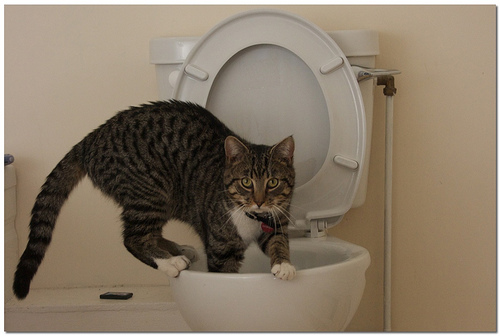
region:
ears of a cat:
[219, 133, 299, 162]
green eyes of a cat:
[232, 175, 282, 192]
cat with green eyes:
[72, 90, 317, 290]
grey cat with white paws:
[3, 96, 309, 312]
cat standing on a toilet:
[17, 95, 307, 303]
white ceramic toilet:
[146, 11, 382, 328]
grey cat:
[0, 87, 306, 333]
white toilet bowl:
[153, 237, 385, 334]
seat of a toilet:
[175, 10, 369, 240]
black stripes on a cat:
[86, 110, 226, 215]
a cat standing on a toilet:
[6, 10, 381, 308]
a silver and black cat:
[10, 95, 305, 305]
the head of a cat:
[219, 132, 299, 215]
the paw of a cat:
[266, 257, 302, 287]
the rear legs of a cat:
[114, 213, 204, 284]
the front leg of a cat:
[257, 231, 302, 287]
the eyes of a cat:
[233, 174, 280, 190]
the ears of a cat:
[219, 130, 297, 162]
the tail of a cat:
[6, 139, 90, 302]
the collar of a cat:
[238, 209, 278, 234]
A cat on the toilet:
[14, 101, 296, 299]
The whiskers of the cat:
[228, 203, 293, 228]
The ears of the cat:
[223, 134, 294, 158]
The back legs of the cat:
[121, 209, 193, 274]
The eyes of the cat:
[238, 175, 280, 187]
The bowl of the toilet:
[173, 237, 367, 332]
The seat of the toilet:
[176, 18, 362, 231]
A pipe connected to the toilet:
[374, 72, 394, 333]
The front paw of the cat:
[271, 260, 296, 281]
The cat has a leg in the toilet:
[204, 240, 247, 274]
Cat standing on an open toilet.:
[10, 95, 295, 295]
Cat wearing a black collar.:
[237, 207, 278, 228]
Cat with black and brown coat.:
[10, 100, 295, 300]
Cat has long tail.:
[10, 140, 85, 300]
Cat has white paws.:
[150, 250, 185, 280]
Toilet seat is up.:
[300, 10, 371, 230]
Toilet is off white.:
[295, 5, 376, 325]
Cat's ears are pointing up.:
[220, 130, 295, 160]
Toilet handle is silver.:
[350, 60, 400, 80]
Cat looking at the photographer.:
[215, 125, 305, 235]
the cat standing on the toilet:
[15, 98, 295, 297]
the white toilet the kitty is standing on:
[147, 32, 373, 334]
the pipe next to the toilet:
[378, 71, 399, 331]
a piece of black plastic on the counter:
[97, 287, 133, 299]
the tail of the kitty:
[12, 158, 75, 302]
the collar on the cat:
[238, 210, 283, 235]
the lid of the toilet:
[171, 19, 360, 233]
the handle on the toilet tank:
[350, 53, 402, 83]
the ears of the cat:
[222, 136, 295, 158]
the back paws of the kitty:
[126, 238, 206, 283]